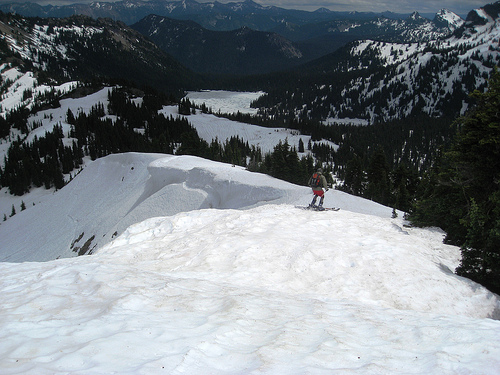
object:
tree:
[366, 145, 393, 207]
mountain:
[0, 16, 183, 107]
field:
[189, 64, 377, 165]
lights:
[75, 95, 203, 153]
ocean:
[284, 203, 404, 331]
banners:
[0, 0, 499, 373]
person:
[307, 168, 328, 211]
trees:
[402, 61, 499, 228]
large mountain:
[247, 0, 500, 128]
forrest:
[2, 0, 498, 297]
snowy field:
[0, 202, 498, 374]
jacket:
[308, 171, 328, 191]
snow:
[23, 21, 133, 94]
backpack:
[310, 173, 322, 188]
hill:
[0, 209, 500, 375]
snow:
[0, 90, 497, 372]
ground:
[2, 152, 497, 373]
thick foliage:
[376, 149, 432, 208]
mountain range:
[4, 1, 481, 226]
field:
[0, 192, 500, 375]